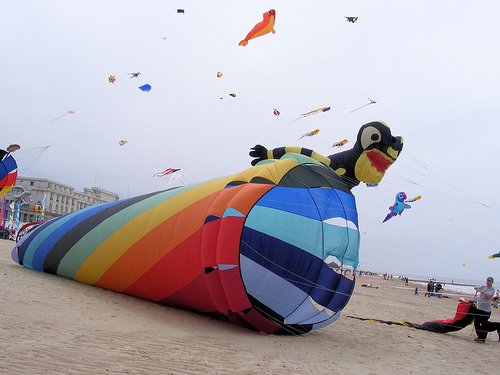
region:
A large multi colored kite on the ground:
[11, 152, 363, 339]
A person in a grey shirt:
[470, 276, 495, 345]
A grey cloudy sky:
[1, 1, 498, 286]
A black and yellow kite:
[248, 120, 402, 190]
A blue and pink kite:
[381, 190, 409, 225]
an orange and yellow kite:
[239, 8, 277, 45]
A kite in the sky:
[333, 136, 349, 147]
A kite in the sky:
[301, 128, 320, 140]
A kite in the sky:
[344, 14, 359, 23]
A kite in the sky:
[118, 138, 127, 145]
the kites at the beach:
[1, 0, 498, 374]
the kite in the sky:
[382, 191, 422, 223]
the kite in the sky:
[340, 14, 358, 23]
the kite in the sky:
[330, 139, 347, 148]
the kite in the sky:
[300, 129, 320, 139]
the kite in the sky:
[292, 106, 331, 123]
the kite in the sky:
[238, 9, 275, 45]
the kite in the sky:
[138, 82, 152, 92]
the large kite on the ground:
[10, 121, 405, 336]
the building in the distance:
[7, 173, 117, 233]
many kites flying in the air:
[55, 4, 388, 142]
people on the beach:
[367, 248, 442, 305]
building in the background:
[0, 162, 131, 213]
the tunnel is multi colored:
[2, 160, 378, 353]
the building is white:
[8, 172, 108, 222]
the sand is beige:
[22, 282, 251, 364]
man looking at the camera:
[460, 263, 497, 323]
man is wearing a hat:
[472, 272, 493, 288]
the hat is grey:
[477, 269, 497, 289]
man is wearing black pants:
[460, 306, 499, 347]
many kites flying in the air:
[99, 4, 444, 230]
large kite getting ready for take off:
[26, 128, 418, 341]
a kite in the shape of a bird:
[375, 185, 422, 230]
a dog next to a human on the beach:
[468, 310, 499, 337]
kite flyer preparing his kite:
[437, 274, 496, 338]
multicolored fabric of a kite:
[60, 216, 196, 282]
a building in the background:
[32, 179, 87, 206]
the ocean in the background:
[454, 276, 469, 291]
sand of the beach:
[33, 293, 164, 361]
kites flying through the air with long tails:
[297, 103, 346, 150]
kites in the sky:
[3, 3, 487, 150]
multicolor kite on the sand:
[5, 105, 405, 373]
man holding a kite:
[373, 272, 499, 352]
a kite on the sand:
[363, 287, 480, 342]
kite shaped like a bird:
[382, 184, 428, 229]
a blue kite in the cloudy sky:
[129, 73, 165, 104]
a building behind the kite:
[3, 120, 403, 341]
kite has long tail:
[281, 98, 338, 123]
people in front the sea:
[363, 214, 499, 356]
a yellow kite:
[106, 130, 137, 156]